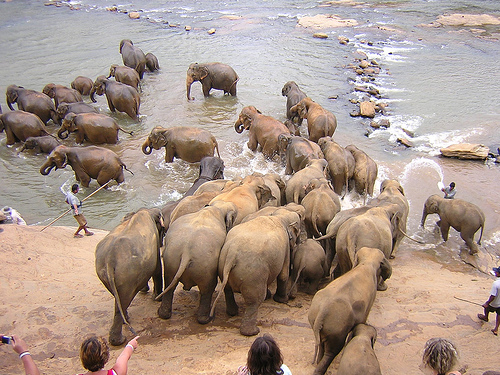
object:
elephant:
[187, 62, 240, 100]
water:
[1, 0, 108, 77]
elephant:
[120, 38, 146, 74]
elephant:
[88, 75, 139, 112]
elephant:
[142, 125, 220, 163]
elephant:
[40, 144, 129, 189]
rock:
[313, 32, 328, 39]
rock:
[360, 101, 376, 118]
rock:
[128, 11, 140, 20]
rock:
[441, 142, 490, 160]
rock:
[208, 28, 217, 34]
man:
[65, 184, 93, 238]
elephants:
[2, 39, 485, 374]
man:
[478, 266, 500, 335]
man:
[442, 182, 456, 200]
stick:
[38, 209, 71, 233]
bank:
[1, 230, 500, 375]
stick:
[453, 296, 482, 308]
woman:
[77, 337, 141, 375]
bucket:
[438, 182, 444, 191]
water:
[401, 158, 444, 182]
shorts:
[74, 213, 87, 226]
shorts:
[485, 305, 500, 315]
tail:
[227, 76, 239, 94]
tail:
[135, 62, 142, 72]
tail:
[134, 98, 140, 115]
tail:
[213, 139, 220, 158]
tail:
[120, 164, 134, 175]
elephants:
[5, 83, 53, 117]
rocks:
[359, 60, 370, 68]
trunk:
[142, 138, 152, 155]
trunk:
[40, 160, 55, 176]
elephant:
[58, 112, 133, 145]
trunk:
[58, 126, 69, 139]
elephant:
[235, 106, 292, 157]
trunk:
[235, 119, 245, 134]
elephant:
[145, 53, 160, 72]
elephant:
[18, 135, 60, 155]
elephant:
[95, 208, 165, 344]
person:
[0, 333, 40, 375]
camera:
[0, 335, 12, 343]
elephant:
[217, 210, 303, 336]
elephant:
[160, 201, 237, 324]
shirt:
[76, 369, 116, 374]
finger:
[133, 335, 140, 340]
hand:
[11, 336, 27, 354]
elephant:
[421, 194, 486, 254]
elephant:
[375, 179, 410, 213]